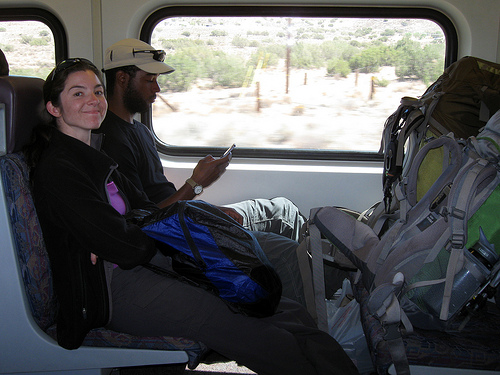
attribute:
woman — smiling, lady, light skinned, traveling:
[28, 57, 361, 374]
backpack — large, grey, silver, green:
[302, 107, 500, 342]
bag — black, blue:
[131, 198, 281, 317]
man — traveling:
[102, 35, 307, 296]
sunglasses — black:
[134, 46, 166, 64]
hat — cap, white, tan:
[95, 37, 179, 75]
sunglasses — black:
[52, 57, 100, 82]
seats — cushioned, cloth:
[0, 77, 208, 372]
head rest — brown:
[2, 75, 56, 153]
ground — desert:
[0, 15, 453, 151]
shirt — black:
[33, 135, 158, 349]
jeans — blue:
[219, 197, 309, 291]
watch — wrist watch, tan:
[184, 178, 204, 195]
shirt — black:
[98, 111, 182, 207]